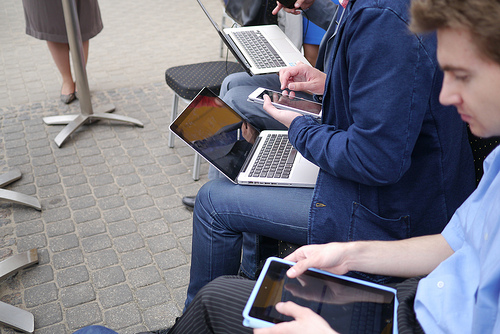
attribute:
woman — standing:
[23, 0, 103, 105]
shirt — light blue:
[406, 143, 498, 330]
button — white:
[431, 277, 445, 291]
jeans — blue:
[130, 161, 315, 298]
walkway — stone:
[21, 6, 251, 330]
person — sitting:
[201, 3, 498, 332]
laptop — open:
[196, 2, 313, 77]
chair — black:
[164, 0, 267, 180]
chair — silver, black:
[166, 60, 253, 180]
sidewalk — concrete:
[3, 73, 226, 330]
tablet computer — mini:
[250, 86, 323, 119]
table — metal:
[40, 2, 144, 144]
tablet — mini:
[250, 89, 324, 120]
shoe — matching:
[71, 83, 80, 103]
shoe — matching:
[58, 80, 76, 101]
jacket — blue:
[286, 4, 479, 242]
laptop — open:
[171, 87, 323, 187]